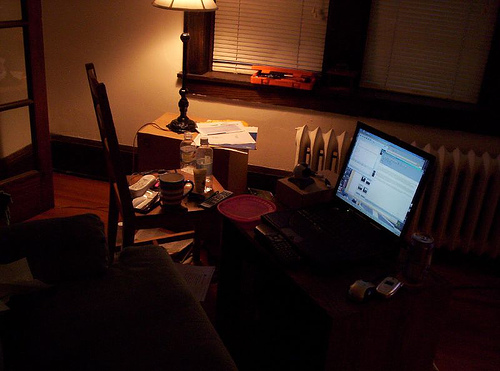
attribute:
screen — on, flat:
[332, 127, 428, 236]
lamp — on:
[149, 0, 218, 134]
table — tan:
[135, 109, 249, 273]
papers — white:
[194, 119, 256, 151]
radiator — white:
[292, 123, 499, 262]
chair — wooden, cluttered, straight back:
[83, 60, 234, 279]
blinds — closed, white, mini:
[359, 0, 499, 104]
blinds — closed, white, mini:
[211, 1, 328, 81]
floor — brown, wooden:
[17, 169, 499, 370]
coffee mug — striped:
[157, 170, 192, 211]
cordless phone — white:
[129, 174, 157, 197]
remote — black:
[200, 188, 233, 210]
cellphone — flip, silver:
[373, 273, 403, 297]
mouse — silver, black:
[344, 277, 376, 304]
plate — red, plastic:
[214, 192, 277, 224]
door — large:
[1, 0, 55, 227]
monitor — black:
[330, 118, 436, 244]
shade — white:
[152, 0, 219, 13]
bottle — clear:
[192, 134, 213, 192]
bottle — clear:
[178, 128, 197, 188]